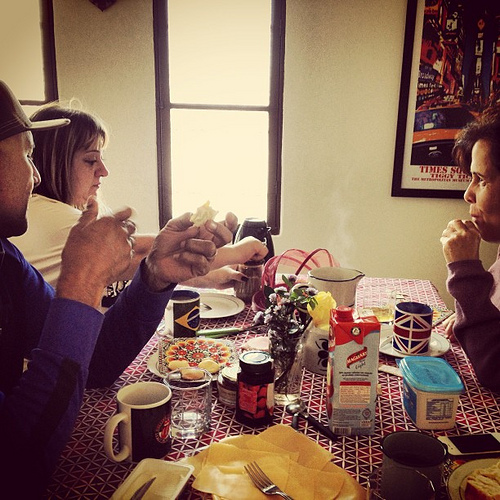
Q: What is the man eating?
A: A biscuit.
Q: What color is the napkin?
A: Yellow.